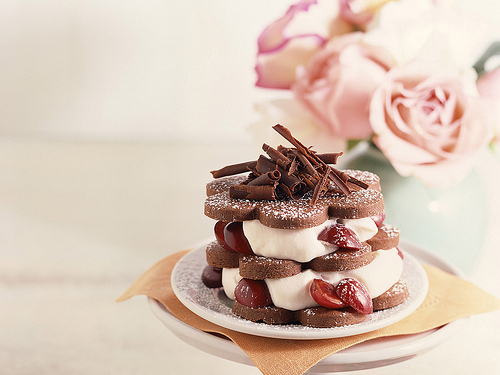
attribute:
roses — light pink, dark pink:
[251, 0, 477, 158]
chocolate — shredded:
[202, 130, 365, 231]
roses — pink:
[282, 29, 491, 192]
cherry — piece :
[308, 274, 380, 316]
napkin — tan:
[252, 349, 290, 373]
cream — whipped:
[365, 270, 391, 289]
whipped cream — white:
[241, 218, 379, 264]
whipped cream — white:
[221, 248, 402, 310]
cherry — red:
[336, 277, 375, 313]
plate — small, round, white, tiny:
[170, 243, 429, 340]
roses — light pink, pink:
[249, 1, 499, 195]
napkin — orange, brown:
[118, 248, 498, 373]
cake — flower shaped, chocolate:
[202, 166, 386, 232]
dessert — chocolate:
[200, 122, 408, 329]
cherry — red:
[311, 278, 345, 312]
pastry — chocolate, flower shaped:
[202, 166, 386, 230]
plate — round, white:
[145, 241, 465, 365]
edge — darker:
[251, 0, 328, 91]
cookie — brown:
[202, 168, 386, 229]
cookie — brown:
[203, 222, 401, 281]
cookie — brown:
[231, 279, 410, 329]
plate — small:
[145, 235, 473, 372]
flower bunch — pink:
[251, 0, 479, 190]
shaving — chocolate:
[272, 122, 352, 197]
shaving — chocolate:
[225, 183, 276, 201]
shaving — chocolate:
[243, 167, 281, 185]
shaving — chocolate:
[308, 162, 332, 208]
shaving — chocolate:
[254, 157, 299, 188]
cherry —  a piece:
[318, 223, 361, 253]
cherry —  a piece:
[235, 276, 260, 303]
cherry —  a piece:
[217, 226, 244, 261]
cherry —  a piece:
[221, 241, 234, 258]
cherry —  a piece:
[188, 267, 212, 287]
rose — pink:
[379, 75, 465, 181]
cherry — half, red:
[310, 285, 340, 304]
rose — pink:
[373, 92, 459, 161]